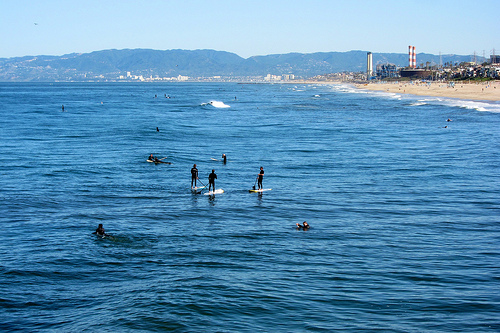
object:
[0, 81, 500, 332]
blue water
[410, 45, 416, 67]
smoke stack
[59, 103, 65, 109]
person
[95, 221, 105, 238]
person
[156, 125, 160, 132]
person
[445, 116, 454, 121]
person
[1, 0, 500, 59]
sky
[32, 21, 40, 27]
plane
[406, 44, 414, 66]
columns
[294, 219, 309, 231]
person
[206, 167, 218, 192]
person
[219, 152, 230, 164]
person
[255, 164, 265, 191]
person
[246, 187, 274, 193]
board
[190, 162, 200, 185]
person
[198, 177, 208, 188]
paddle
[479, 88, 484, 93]
people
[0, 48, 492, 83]
mountain range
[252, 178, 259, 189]
paddle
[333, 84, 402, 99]
waves ashore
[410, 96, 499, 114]
waves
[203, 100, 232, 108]
waves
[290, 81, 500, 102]
shore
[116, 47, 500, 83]
city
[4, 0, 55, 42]
air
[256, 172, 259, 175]
hands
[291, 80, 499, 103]
beach